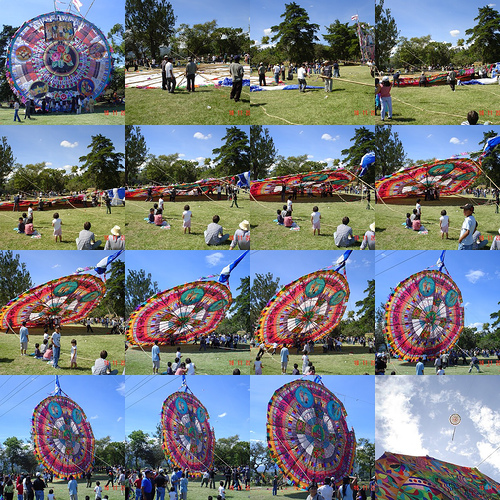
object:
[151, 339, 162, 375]
person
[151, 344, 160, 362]
shirt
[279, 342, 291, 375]
person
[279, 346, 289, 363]
shirt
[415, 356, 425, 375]
person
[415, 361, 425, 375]
shirt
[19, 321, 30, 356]
person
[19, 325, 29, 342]
shirt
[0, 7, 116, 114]
kite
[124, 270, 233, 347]
kite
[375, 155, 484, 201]
kite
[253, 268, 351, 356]
kite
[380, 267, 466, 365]
kite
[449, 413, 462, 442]
kite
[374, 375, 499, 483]
sky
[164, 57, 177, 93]
person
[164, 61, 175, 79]
shirt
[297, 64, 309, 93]
person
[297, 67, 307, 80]
shirt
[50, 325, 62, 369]
person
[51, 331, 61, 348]
shirt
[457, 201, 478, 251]
person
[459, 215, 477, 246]
shirt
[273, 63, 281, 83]
person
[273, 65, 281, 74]
shirt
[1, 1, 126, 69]
sky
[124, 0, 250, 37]
sky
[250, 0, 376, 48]
sky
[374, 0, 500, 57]
sky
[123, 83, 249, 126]
grass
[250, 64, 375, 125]
grass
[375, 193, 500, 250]
grass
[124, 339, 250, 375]
grass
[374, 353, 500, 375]
grass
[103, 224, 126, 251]
person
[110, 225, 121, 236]
hat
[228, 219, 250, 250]
person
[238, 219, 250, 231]
hat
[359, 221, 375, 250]
person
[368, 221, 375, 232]
hat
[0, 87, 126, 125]
ground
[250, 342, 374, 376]
ground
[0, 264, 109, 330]
kite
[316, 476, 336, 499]
person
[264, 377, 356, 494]
kite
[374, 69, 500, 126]
grass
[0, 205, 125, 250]
grass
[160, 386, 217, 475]
kite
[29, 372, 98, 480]
kite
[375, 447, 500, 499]
kite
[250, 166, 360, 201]
kite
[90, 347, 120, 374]
person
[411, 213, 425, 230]
person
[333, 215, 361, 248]
person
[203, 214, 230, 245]
person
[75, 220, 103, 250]
person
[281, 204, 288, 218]
person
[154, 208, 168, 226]
person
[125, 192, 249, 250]
grass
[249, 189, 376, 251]
grass